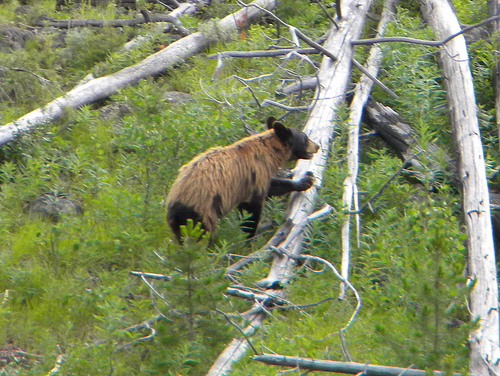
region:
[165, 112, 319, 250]
Brown bear in woods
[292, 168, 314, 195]
Bear paw on tree trunk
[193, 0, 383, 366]
Dead tree trunk on ground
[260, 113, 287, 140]
Black ears on bear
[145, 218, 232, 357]
Sapling evergreen tree on ground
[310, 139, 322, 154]
Black nose on bear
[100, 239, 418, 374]
Broken dead branches on ground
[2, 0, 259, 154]
Fallen tree on ground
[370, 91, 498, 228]
Rotting log on ground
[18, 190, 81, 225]
Rock on clearing ground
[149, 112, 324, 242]
bear in the woods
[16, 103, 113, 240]
plants in the woods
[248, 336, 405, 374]
branch lying on the ground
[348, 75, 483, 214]
trunk of a tree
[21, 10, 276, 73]
trunk of a tree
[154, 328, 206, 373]
green plant on ground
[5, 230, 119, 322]
yellow plants on the ground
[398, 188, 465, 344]
plant standing upright near log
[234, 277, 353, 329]
branches from the trees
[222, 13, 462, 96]
trunk with branches extending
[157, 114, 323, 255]
black bear shedding fur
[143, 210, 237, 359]
short green pine tree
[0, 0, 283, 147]
sun bleached fallen log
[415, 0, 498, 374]
sun bleached fallen log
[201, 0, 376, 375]
sun bleached fallen log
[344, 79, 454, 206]
black and tan fallen log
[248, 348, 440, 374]
small sun bleached fallen log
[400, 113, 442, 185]
tall leafy green weed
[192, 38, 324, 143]
gnarly sun bleached branch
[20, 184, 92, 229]
big lumpy grey stone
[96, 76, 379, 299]
the bear has wet paws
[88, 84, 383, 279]
this is a bear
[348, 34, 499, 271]
the tree has fallen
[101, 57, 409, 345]
there is one bear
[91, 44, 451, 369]
the bear climbs a tree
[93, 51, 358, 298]
the bear paws the tree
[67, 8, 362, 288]
grizzly bear is brown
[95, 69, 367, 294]
bear in the woods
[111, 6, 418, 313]
bear has black spots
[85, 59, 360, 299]
fallen tree with a bear